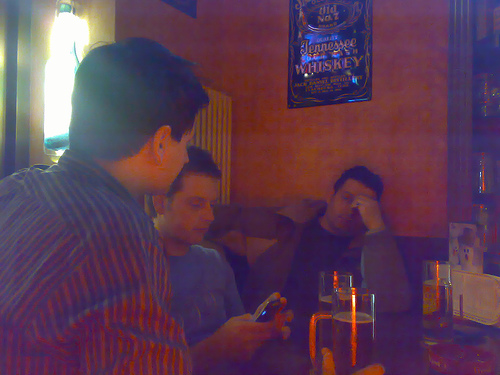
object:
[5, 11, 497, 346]
pub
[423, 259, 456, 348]
glasses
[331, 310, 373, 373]
beer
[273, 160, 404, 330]
man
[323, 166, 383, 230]
head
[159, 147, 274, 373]
man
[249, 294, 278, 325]
cellphone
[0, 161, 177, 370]
shirt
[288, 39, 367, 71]
tennessee whiskey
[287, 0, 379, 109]
sign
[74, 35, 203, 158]
hair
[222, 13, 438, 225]
wallpaper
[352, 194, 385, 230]
hand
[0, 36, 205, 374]
man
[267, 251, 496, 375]
table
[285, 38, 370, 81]
jack daniels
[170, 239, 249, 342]
shirt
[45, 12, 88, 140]
light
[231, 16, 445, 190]
wall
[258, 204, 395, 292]
jacket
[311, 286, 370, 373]
mug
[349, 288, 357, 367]
light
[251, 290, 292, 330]
phone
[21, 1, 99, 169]
window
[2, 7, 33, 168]
frame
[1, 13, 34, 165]
door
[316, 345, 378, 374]
hand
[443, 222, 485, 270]
picture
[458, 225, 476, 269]
snowman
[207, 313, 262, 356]
hand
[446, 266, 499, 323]
menus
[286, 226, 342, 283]
shirt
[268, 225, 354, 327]
torso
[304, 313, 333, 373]
handle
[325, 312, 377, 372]
liquid